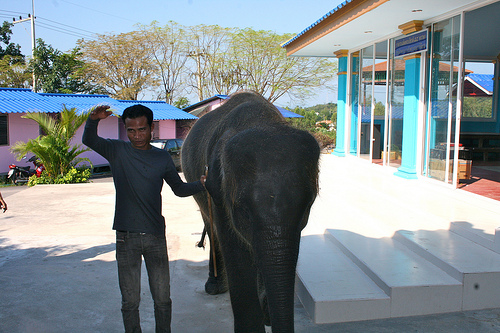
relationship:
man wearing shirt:
[79, 94, 217, 330] [79, 117, 198, 238]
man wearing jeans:
[79, 94, 217, 330] [112, 227, 172, 329]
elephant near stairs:
[175, 85, 322, 329] [292, 152, 496, 326]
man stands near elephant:
[79, 94, 217, 330] [175, 85, 322, 329]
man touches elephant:
[79, 94, 217, 330] [175, 85, 322, 329]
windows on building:
[442, 10, 496, 200] [279, 3, 498, 213]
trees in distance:
[206, 33, 283, 101] [3, 0, 340, 108]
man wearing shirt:
[79, 94, 217, 330] [82, 118, 208, 228]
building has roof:
[2, 83, 202, 183] [0, 86, 200, 125]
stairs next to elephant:
[292, 152, 496, 326] [175, 85, 322, 329]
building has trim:
[279, 3, 498, 213] [412, 51, 427, 180]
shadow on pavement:
[2, 231, 497, 330] [2, 183, 493, 330]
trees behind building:
[0, 17, 337, 100] [2, 83, 202, 183]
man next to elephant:
[79, 94, 217, 330] [175, 85, 322, 329]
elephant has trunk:
[175, 85, 322, 329] [253, 217, 303, 330]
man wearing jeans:
[79, 94, 217, 330] [114, 231, 173, 331]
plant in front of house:
[6, 98, 96, 188] [2, 82, 200, 177]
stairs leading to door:
[298, 215, 497, 326] [456, 0, 497, 196]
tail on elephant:
[195, 224, 209, 250] [175, 85, 322, 329]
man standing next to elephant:
[79, 94, 217, 330] [175, 85, 322, 329]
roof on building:
[0, 83, 203, 123] [2, 83, 202, 183]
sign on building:
[389, 23, 434, 61] [2, 83, 202, 183]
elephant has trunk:
[175, 85, 322, 329] [249, 216, 297, 330]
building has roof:
[2, 83, 202, 183] [1, 90, 199, 112]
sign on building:
[389, 23, 434, 61] [286, 1, 499, 199]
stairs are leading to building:
[298, 215, 497, 326] [283, 5, 499, 236]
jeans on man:
[114, 231, 173, 331] [79, 94, 217, 330]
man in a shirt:
[79, 94, 217, 330] [82, 118, 208, 228]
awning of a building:
[0, 92, 193, 121] [0, 87, 190, 180]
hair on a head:
[120, 105, 152, 118] [115, 102, 157, 152]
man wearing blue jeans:
[79, 94, 217, 330] [114, 232, 178, 331]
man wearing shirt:
[79, 94, 217, 330] [75, 117, 205, 231]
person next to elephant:
[78, 100, 206, 329] [175, 85, 322, 329]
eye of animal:
[238, 197, 255, 218] [176, 86, 325, 327]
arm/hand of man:
[79, 102, 115, 161] [79, 94, 217, 330]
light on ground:
[59, 216, 95, 241] [26, 186, 107, 310]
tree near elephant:
[24, 106, 84, 183] [175, 85, 322, 329]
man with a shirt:
[79, 94, 217, 330] [79, 115, 181, 218]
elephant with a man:
[175, 85, 322, 329] [79, 94, 217, 330]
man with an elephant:
[79, 94, 217, 330] [175, 85, 322, 329]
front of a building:
[342, 10, 478, 196] [274, 2, 484, 192]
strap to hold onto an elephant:
[196, 135, 224, 281] [175, 85, 322, 329]